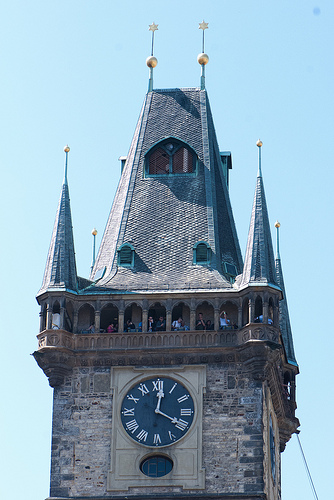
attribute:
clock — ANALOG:
[116, 366, 197, 491]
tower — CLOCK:
[8, 35, 318, 498]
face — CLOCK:
[128, 386, 192, 450]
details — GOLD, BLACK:
[133, 427, 149, 439]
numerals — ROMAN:
[177, 422, 189, 431]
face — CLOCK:
[118, 375, 196, 448]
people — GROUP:
[82, 309, 244, 332]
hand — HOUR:
[156, 391, 174, 426]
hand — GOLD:
[157, 398, 170, 423]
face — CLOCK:
[117, 379, 192, 443]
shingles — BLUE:
[31, 68, 291, 293]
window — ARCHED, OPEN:
[146, 133, 202, 179]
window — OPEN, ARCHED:
[145, 130, 197, 185]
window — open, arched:
[121, 299, 144, 336]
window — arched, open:
[148, 302, 168, 331]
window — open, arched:
[170, 302, 191, 331]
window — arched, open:
[194, 301, 215, 331]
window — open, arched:
[238, 297, 250, 326]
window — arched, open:
[253, 291, 263, 326]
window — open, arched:
[266, 296, 275, 326]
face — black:
[121, 374, 193, 446]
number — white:
[150, 379, 165, 392]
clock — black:
[116, 370, 201, 450]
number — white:
[169, 382, 178, 393]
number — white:
[175, 393, 189, 403]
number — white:
[178, 406, 193, 416]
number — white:
[174, 418, 187, 431]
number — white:
[166, 429, 177, 441]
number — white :
[152, 433, 164, 445]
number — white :
[137, 430, 147, 445]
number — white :
[124, 418, 141, 435]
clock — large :
[118, 370, 194, 441]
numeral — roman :
[166, 429, 176, 440]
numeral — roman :
[179, 407, 197, 418]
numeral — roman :
[123, 409, 132, 419]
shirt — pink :
[106, 323, 117, 334]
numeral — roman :
[168, 382, 179, 395]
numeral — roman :
[178, 394, 192, 403]